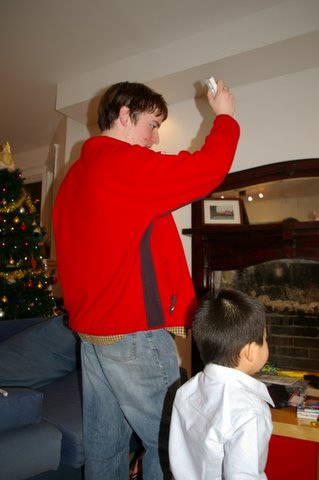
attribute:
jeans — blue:
[71, 314, 190, 473]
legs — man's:
[72, 299, 188, 479]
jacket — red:
[51, 112, 241, 333]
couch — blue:
[1, 313, 188, 477]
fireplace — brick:
[212, 259, 317, 378]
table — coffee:
[212, 303, 314, 479]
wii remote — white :
[201, 73, 239, 121]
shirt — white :
[168, 362, 273, 477]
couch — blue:
[2, 301, 99, 477]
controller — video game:
[205, 76, 216, 96]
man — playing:
[48, 74, 239, 478]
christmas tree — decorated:
[0, 140, 62, 319]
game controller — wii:
[205, 74, 217, 94]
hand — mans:
[205, 81, 236, 115]